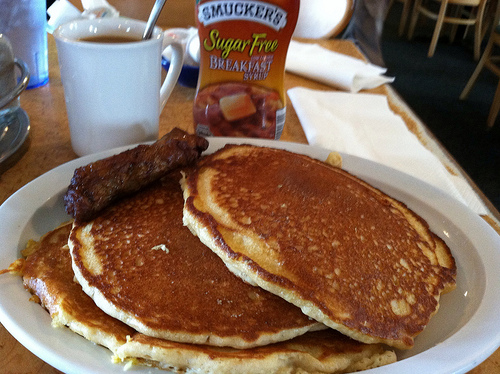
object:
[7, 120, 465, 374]
food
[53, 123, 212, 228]
piece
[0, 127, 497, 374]
plate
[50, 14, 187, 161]
cup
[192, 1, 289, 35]
name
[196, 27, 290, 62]
letters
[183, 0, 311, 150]
bottle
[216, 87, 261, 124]
butter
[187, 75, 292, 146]
picture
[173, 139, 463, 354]
pancakes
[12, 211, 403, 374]
pancake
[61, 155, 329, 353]
pancake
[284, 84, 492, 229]
handkerchief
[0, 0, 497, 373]
table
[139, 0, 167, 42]
spoon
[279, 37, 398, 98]
napkin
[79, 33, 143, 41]
coffee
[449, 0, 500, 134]
chair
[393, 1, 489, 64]
chair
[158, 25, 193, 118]
creamer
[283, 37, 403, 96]
napkins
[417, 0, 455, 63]
legs